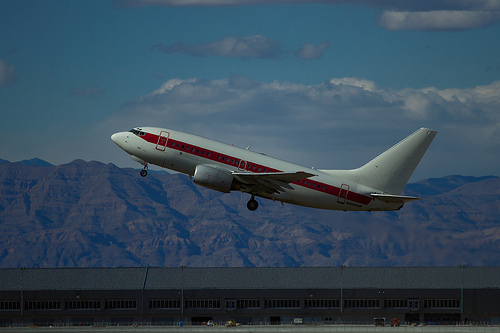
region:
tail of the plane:
[377, 110, 469, 164]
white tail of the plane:
[377, 110, 459, 177]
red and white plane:
[75, 95, 465, 242]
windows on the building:
[255, 292, 305, 312]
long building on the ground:
[107, 245, 482, 330]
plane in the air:
[75, 110, 465, 240]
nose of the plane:
[100, 122, 135, 157]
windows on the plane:
[157, 130, 212, 166]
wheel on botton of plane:
[132, 164, 152, 186]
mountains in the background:
[13, 143, 105, 254]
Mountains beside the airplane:
[2, 160, 499, 265]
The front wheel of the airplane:
[138, 160, 148, 177]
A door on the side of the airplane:
[156, 129, 168, 151]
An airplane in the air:
[113, 125, 438, 212]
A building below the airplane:
[0, 265, 498, 322]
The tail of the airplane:
[321, 128, 436, 189]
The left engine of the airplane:
[191, 166, 236, 188]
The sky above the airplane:
[0, 3, 496, 155]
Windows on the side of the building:
[8, 300, 458, 308]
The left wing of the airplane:
[231, 168, 314, 190]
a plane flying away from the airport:
[101, 115, 437, 215]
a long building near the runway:
[8, 268, 499, 320]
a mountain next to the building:
[3, 156, 497, 268]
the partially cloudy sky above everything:
[2, 2, 499, 177]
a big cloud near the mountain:
[146, 78, 497, 172]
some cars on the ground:
[370, 314, 403, 331]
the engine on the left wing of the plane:
[188, 160, 239, 198]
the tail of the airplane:
[360, 120, 435, 192]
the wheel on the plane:
[237, 192, 257, 209]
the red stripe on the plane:
[143, 135, 366, 211]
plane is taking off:
[108, 118, 448, 249]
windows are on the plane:
[165, 135, 232, 165]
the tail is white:
[360, 135, 455, 190]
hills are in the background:
[61, 180, 460, 268]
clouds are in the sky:
[240, 51, 470, 131]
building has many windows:
[16, 278, 474, 330]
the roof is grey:
[152, 268, 252, 285]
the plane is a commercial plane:
[106, 105, 451, 232]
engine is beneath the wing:
[187, 165, 239, 195]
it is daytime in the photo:
[7, 8, 494, 332]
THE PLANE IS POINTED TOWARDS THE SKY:
[97, 90, 442, 228]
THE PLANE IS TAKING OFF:
[96, 93, 444, 231]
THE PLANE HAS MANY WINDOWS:
[123, 125, 375, 210]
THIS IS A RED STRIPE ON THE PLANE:
[123, 120, 371, 220]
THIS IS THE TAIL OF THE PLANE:
[332, 121, 442, 227]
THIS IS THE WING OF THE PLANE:
[228, 157, 311, 198]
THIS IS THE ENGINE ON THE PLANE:
[185, 157, 236, 198]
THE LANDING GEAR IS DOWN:
[135, 160, 267, 216]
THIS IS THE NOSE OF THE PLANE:
[97, 116, 153, 161]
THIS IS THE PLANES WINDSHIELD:
[126, 125, 156, 142]